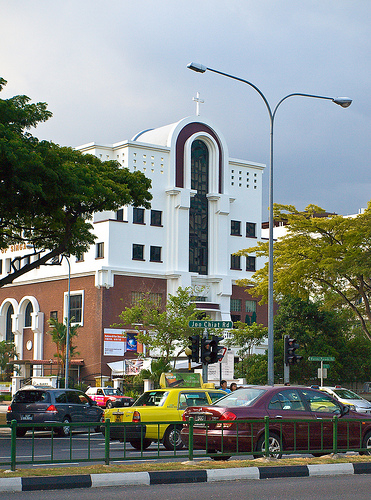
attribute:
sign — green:
[192, 314, 241, 334]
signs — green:
[308, 349, 335, 383]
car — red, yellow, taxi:
[184, 379, 367, 456]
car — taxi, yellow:
[108, 385, 246, 447]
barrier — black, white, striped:
[0, 459, 367, 499]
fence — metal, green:
[7, 412, 370, 474]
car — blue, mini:
[8, 386, 103, 438]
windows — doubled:
[128, 212, 267, 273]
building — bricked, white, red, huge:
[1, 114, 294, 388]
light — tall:
[188, 62, 370, 389]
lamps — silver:
[175, 60, 361, 108]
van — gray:
[10, 391, 106, 439]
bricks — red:
[0, 281, 275, 391]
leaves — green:
[284, 232, 330, 294]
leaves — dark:
[19, 163, 83, 202]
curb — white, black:
[8, 454, 368, 489]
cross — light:
[192, 90, 206, 110]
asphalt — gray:
[2, 473, 368, 499]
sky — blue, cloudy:
[5, 0, 370, 214]